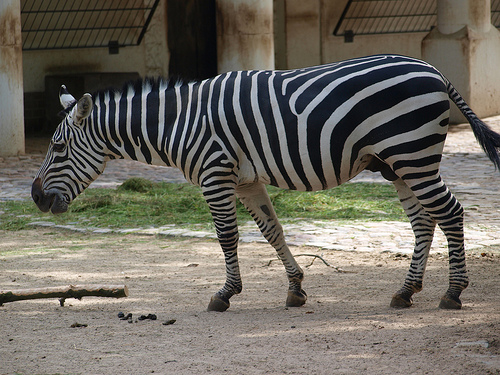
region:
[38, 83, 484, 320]
this is a zebra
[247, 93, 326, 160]
the zebra has white and black strips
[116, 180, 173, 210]
this is a grass area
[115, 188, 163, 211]
the grass is green in color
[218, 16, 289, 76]
this is a pillar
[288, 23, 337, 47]
this is the wall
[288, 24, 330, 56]
the wall is white in color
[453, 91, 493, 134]
this is the tail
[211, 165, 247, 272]
this is a leg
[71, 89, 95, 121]
this is a ear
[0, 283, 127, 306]
tree branch under zebra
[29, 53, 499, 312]
zebra standing over a tree branch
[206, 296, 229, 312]
zebra has a gray hoof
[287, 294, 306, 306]
gray hoof next to hoof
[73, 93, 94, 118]
ear on top of head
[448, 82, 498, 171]
zebra has a long tail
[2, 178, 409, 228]
grass behind zebra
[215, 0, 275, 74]
thick stone column behind zebra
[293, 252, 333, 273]
small twig on the ground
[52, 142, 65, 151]
black eye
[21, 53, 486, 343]
the zebra on the sand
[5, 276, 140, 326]
the branch on the sand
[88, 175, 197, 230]
the grass behind the zebra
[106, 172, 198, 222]
the grass is cut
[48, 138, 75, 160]
the eye of the zebra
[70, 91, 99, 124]
the ear of the zebra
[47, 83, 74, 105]
the ear of the zebra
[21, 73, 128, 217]
the head of the zebra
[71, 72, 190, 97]
the mane of the zebra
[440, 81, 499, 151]
the tail of the zebra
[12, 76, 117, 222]
Zebra with its head down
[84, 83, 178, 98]
spiked hair on the zebras back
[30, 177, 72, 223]
zebra with its mouth closed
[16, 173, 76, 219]
zebra with a black nose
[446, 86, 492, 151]
zebra with a bushy tail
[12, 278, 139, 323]
branch next to the zebra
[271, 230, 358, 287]
twig next to the zebra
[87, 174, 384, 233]
grassy patch in the field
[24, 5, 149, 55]
metal rail on the building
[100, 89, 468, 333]
zebra standing in the dirt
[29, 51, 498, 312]
A zebra on the dirt.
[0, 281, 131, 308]
A branch on the ground.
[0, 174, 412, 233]
A patch of grass.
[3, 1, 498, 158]
A building in the back.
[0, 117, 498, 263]
A stone walk way.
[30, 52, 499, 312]
A zebra on a road.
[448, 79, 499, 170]
A zebras bushy tail.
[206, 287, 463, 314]
A zebras four hoofs.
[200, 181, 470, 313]
A zebras four legs.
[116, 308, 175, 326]
Rocks on the ground.